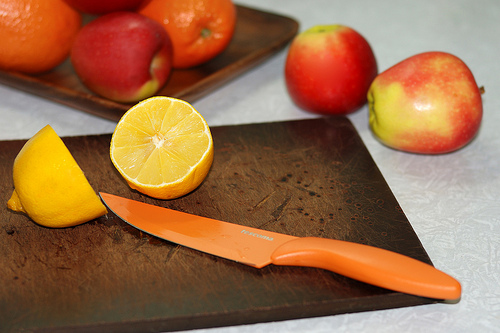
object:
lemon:
[109, 95, 214, 200]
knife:
[95, 190, 469, 301]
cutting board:
[3, 117, 448, 333]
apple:
[68, 12, 176, 104]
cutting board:
[0, 0, 304, 123]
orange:
[139, 1, 236, 69]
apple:
[285, 25, 377, 116]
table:
[2, 2, 498, 331]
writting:
[239, 227, 275, 241]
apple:
[368, 48, 486, 154]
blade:
[100, 192, 299, 269]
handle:
[273, 236, 470, 302]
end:
[201, 26, 212, 39]